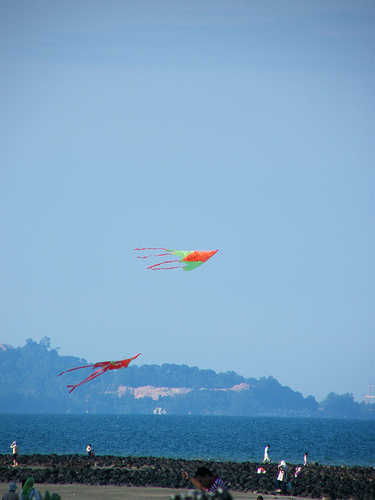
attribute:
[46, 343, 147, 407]
kite — red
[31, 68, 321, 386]
sky — blue, clear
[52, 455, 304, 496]
beach — rocky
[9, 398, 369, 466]
water — blue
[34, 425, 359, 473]
people — standing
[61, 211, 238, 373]
kites — flying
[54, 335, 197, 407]
kite — red, green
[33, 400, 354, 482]
water — choppy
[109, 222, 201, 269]
kite — orange, yellow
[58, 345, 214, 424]
kite — red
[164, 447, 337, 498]
people — standing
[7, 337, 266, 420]
sky — hazy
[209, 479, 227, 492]
shirt — red, white, striped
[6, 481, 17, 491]
hat — blue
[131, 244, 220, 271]
kite — red, green, color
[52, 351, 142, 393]
kite — color, red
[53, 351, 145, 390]
kite — wavy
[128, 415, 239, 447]
water — blue, color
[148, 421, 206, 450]
waves — small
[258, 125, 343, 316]
sky — blue, color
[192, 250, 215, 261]
kite — orange, part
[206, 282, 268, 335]
sky — section, blue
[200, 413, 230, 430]
sea — part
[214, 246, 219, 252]
kite — tip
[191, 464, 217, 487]
head — man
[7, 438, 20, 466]
man — old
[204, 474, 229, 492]
shirt — section, stripped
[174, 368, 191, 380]
forest — section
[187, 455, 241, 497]
shirt — striped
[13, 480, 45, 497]
hat — green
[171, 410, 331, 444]
ocean — blue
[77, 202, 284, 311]
kite — green, red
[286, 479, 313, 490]
object — blue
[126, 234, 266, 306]
kite — green, orange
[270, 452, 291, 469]
scarf — white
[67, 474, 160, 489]
sand — tan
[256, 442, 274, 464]
man — one